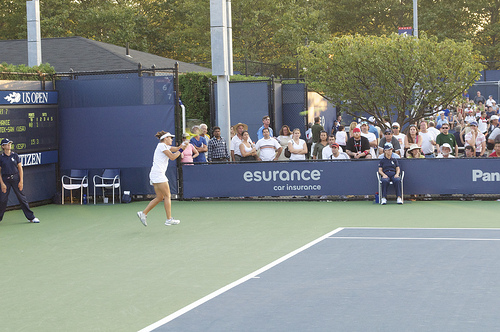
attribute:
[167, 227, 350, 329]
line — white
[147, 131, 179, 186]
uniform — white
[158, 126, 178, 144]
visor — white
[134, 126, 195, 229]
player — tennis player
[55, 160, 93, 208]
chair — white and blue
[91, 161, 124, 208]
chair — white and blue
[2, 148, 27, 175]
shirt — blue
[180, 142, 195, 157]
shirt — pink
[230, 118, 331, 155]
people — standing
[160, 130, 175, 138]
visor — white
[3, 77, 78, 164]
scoreboard — black, yellow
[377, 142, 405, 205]
man — a referee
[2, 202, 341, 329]
green court — here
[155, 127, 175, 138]
visor — white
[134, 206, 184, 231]
tennis shoes — white, gray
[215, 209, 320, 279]
line — white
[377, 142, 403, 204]
woman — sitting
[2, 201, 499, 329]
court — blue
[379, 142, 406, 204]
attendant — court attendant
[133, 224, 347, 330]
line — white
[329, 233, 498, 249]
line — white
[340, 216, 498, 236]
line — white